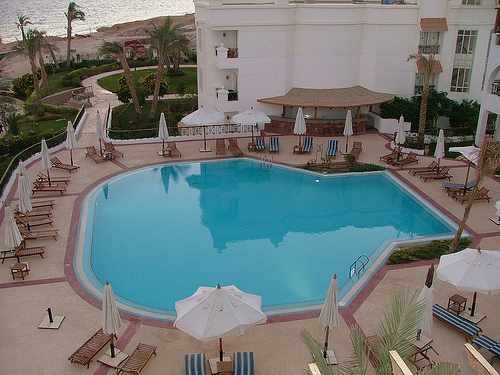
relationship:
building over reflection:
[176, 0, 500, 139] [182, 157, 453, 254]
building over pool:
[176, 0, 500, 139] [79, 154, 450, 342]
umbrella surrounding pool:
[177, 102, 227, 130] [86, 157, 459, 315]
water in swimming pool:
[72, 151, 465, 320] [59, 142, 476, 327]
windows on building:
[459, 1, 484, 6] [188, 2, 497, 147]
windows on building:
[451, 24, 479, 56] [188, 2, 497, 147]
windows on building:
[445, 65, 472, 90] [188, 2, 497, 147]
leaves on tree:
[384, 280, 426, 340] [368, 280, 430, 370]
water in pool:
[72, 151, 465, 320] [75, 147, 475, 334]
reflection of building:
[182, 157, 453, 254] [188, 2, 497, 147]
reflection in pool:
[182, 157, 453, 254] [86, 157, 459, 315]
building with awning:
[165, 4, 471, 146] [257, 84, 397, 107]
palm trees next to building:
[101, 15, 191, 124] [179, 0, 499, 174]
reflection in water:
[182, 157, 453, 254] [72, 151, 465, 320]